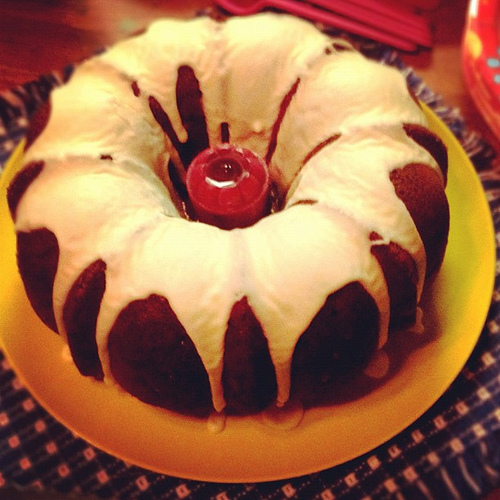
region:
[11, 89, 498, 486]
A bundt cake sitting on a yellow plate.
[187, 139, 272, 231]
A red candle in the center of a cake.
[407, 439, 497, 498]
A blue checkered tablecloth.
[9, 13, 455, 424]
White frosting on a bundt cake.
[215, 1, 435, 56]
Red spoon besides a bundt cake.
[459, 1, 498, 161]
Red designed party plates on a table.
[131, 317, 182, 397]
Chocolate flavored brown cake.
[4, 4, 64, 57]
Wooden wood grain table top.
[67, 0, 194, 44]
Light reflection in a tabletop.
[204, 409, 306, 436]
Puddles of white frosting near a bundt cake.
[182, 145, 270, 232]
Candle inside of the cake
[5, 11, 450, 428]
Chocolate cake with icing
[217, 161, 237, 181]
Black stick in the candle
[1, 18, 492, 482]
Plate with cake on the table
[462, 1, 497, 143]
Stack of plastic plates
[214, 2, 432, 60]
Stack of utensils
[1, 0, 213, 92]
Wooden table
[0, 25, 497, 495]
Napkin with diamond designs on the table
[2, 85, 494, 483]
Yellow plate on the table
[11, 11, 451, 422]
Piece of desert on the plate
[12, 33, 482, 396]
Cake on a yellow plate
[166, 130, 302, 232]
red candle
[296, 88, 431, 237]
White icing on brown cake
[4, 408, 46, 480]
Blue and white plaid table cover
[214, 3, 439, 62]
Red plastic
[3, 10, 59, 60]
Wooden table top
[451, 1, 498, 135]
Red print paper plates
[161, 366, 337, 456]
Icing dripping on a plate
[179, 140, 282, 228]
Melted wax on the candle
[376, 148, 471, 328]
A brown cake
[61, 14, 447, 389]
the cake on the plate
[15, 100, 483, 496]
the plate is yellow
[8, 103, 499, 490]
the plate is circular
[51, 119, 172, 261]
icing on the cake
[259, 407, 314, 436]
icing dripping on the plate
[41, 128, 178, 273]
the icing is white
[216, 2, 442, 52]
plastic eating utensils beside the plate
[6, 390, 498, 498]
the clothe under the plate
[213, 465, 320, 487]
edge of the plate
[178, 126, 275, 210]
candle in middle of cake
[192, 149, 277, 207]
a candle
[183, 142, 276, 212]
the candle is red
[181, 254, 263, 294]
the frosting on the cake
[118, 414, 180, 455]
the plate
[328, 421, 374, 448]
the plate is yellow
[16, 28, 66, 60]
a wooden table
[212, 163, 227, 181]
liquid in the candle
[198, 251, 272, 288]
frosting on the cake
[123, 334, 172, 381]
the cake is chocolate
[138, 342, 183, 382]
the cake is brown